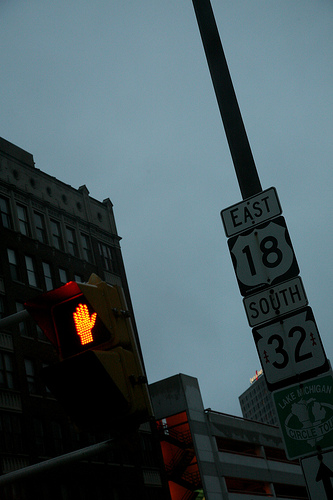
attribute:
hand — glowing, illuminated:
[72, 304, 99, 346]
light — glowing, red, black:
[153, 409, 202, 499]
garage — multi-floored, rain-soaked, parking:
[149, 374, 326, 500]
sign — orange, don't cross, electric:
[38, 285, 131, 348]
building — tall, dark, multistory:
[0, 139, 149, 444]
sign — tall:
[221, 187, 330, 499]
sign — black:
[299, 449, 331, 498]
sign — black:
[222, 186, 282, 241]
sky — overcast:
[0, 2, 331, 420]